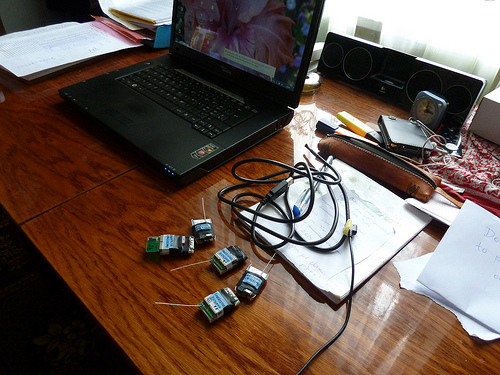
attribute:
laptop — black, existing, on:
[55, 1, 327, 189]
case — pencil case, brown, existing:
[316, 134, 445, 205]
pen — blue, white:
[294, 152, 335, 219]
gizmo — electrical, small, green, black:
[140, 232, 199, 259]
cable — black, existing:
[212, 140, 351, 262]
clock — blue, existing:
[406, 91, 449, 129]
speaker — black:
[315, 28, 486, 135]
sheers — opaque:
[327, 0, 500, 108]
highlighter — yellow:
[335, 107, 385, 152]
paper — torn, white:
[390, 254, 500, 345]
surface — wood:
[3, 52, 498, 375]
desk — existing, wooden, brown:
[2, 34, 498, 374]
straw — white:
[153, 299, 202, 309]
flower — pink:
[175, 0, 300, 77]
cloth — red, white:
[423, 104, 499, 205]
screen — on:
[172, 2, 322, 99]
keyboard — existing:
[112, 62, 266, 141]